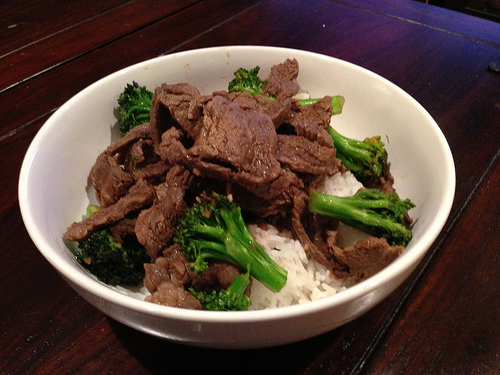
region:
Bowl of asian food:
[16, 33, 461, 345]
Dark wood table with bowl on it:
[0, 9, 489, 369]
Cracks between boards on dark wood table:
[0, 0, 498, 362]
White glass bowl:
[17, 40, 467, 367]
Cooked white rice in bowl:
[188, 138, 391, 312]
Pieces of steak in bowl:
[52, 52, 411, 307]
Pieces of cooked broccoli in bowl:
[77, 65, 416, 315]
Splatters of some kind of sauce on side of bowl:
[132, 41, 241, 88]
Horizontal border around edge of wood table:
[361, 0, 498, 57]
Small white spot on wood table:
[312, 18, 347, 37]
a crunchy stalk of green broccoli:
[186, 200, 290, 285]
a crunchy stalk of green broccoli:
[306, 186, 415, 230]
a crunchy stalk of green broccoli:
[116, 83, 148, 122]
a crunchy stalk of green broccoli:
[82, 225, 131, 277]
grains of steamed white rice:
[278, 243, 308, 296]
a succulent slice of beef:
[205, 97, 272, 179]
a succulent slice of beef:
[89, 150, 125, 196]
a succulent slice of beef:
[290, 119, 320, 172]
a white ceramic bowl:
[39, 134, 85, 202]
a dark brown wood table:
[433, 277, 493, 367]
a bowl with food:
[10, 40, 460, 355]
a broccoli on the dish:
[169, 190, 292, 295]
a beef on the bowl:
[183, 88, 287, 193]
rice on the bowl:
[280, 248, 303, 270]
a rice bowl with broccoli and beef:
[13, 38, 462, 364]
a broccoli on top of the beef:
[306, 188, 414, 239]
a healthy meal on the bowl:
[12, 40, 464, 360]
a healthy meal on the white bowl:
[13, 36, 460, 360]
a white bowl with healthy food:
[13, 39, 460, 366]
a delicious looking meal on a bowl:
[10, 35, 469, 361]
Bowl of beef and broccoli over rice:
[16, 43, 455, 336]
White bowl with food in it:
[17, 43, 455, 351]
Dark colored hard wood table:
[3, 0, 498, 374]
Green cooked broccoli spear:
[174, 189, 293, 291]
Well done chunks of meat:
[154, 83, 277, 183]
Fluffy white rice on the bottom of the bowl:
[254, 220, 326, 307]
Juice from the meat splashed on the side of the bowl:
[136, 43, 248, 99]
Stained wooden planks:
[1, 0, 498, 373]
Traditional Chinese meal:
[19, 42, 457, 339]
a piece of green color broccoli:
[189, 189, 289, 280]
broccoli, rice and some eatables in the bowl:
[68, 56, 395, 284]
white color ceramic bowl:
[30, 30, 457, 312]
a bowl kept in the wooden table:
[53, 32, 461, 372]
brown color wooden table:
[412, 10, 485, 102]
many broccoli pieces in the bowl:
[122, 83, 362, 243]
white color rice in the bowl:
[266, 230, 319, 294]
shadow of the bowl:
[125, 335, 309, 366]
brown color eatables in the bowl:
[169, 99, 279, 173]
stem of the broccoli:
[245, 235, 285, 286]